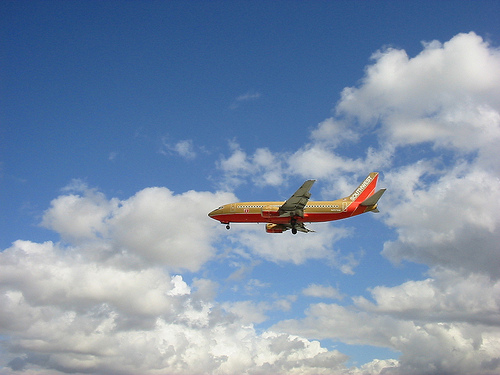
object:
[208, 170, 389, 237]
plane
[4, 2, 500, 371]
sky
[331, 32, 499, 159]
cloud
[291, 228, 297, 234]
wheel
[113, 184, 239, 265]
cloud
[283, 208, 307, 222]
landing gear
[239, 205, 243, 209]
window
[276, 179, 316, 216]
wing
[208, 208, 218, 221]
nose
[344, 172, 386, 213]
tail fin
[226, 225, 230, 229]
front wheel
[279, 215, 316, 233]
wing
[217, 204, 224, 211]
cockpit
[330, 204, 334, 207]
window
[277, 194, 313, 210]
propeller